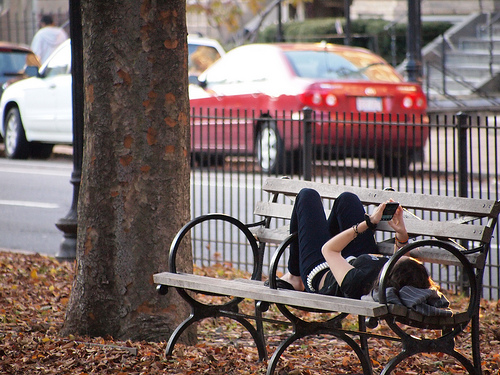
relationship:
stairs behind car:
[399, 11, 497, 105] [193, 35, 436, 184]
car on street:
[193, 35, 436, 184] [7, 144, 498, 297]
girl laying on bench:
[264, 188, 432, 302] [145, 170, 494, 362]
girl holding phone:
[264, 188, 432, 302] [380, 200, 398, 221]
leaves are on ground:
[2, 306, 373, 363] [1, 248, 488, 373]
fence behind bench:
[191, 100, 498, 296] [145, 170, 494, 362]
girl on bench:
[264, 188, 432, 302] [145, 170, 494, 362]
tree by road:
[61, 6, 210, 341] [0, 147, 484, 297]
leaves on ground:
[2, 306, 373, 363] [1, 248, 488, 373]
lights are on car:
[302, 89, 343, 109] [189, 38, 432, 173]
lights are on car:
[396, 88, 430, 111] [189, 38, 432, 173]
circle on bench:
[167, 212, 264, 308] [145, 170, 494, 362]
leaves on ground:
[2, 306, 373, 363] [1, 128, 484, 369]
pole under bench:
[249, 300, 266, 357] [152, 176, 484, 368]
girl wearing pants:
[267, 188, 432, 302] [286, 187, 365, 291]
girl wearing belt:
[267, 188, 432, 302] [303, 254, 356, 286]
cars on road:
[0, 31, 430, 174] [0, 147, 484, 297]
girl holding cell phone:
[264, 188, 432, 302] [380, 200, 400, 222]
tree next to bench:
[61, 6, 192, 342] [152, 176, 484, 368]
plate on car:
[354, 93, 384, 112] [189, 38, 432, 173]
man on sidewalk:
[29, 12, 67, 66] [243, 123, 484, 173]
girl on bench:
[264, 188, 432, 302] [152, 176, 484, 368]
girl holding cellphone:
[264, 188, 432, 302] [378, 200, 399, 218]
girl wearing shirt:
[264, 188, 432, 302] [323, 255, 385, 296]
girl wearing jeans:
[264, 188, 432, 302] [285, 185, 364, 294]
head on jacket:
[377, 250, 428, 284] [367, 285, 451, 310]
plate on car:
[354, 93, 388, 112] [189, 38, 432, 173]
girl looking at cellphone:
[264, 188, 432, 302] [380, 200, 397, 220]